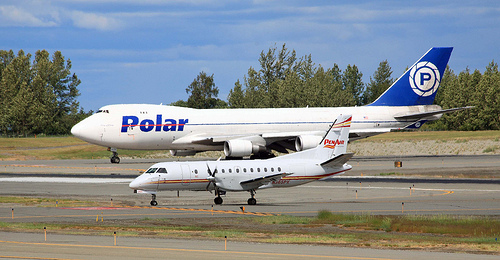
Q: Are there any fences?
A: No, there are no fences.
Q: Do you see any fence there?
A: No, there are no fences.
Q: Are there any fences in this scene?
A: No, there are no fences.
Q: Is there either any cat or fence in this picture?
A: No, there are no fences or cats.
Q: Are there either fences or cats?
A: No, there are no fences or cats.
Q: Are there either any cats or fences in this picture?
A: No, there are no fences or cats.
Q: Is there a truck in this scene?
A: No, there are no trucks.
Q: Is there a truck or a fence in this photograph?
A: No, there are no trucks or fences.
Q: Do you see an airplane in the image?
A: Yes, there is an airplane.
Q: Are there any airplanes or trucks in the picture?
A: Yes, there is an airplane.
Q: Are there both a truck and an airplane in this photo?
A: No, there is an airplane but no trucks.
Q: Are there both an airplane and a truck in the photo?
A: No, there is an airplane but no trucks.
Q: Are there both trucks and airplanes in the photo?
A: No, there is an airplane but no trucks.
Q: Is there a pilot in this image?
A: No, there are no pilots.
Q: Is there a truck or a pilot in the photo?
A: No, there are no pilots or trucks.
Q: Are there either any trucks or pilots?
A: No, there are no pilots or trucks.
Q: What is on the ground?
A: The plane is on the ground.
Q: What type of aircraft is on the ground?
A: The aircraft is an airplane.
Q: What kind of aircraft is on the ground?
A: The aircraft is an airplane.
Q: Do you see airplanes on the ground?
A: Yes, there is an airplane on the ground.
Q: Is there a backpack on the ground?
A: No, there is an airplane on the ground.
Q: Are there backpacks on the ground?
A: No, there is an airplane on the ground.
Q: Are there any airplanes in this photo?
A: Yes, there is an airplane.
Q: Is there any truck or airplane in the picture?
A: Yes, there is an airplane.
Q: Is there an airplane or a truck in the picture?
A: Yes, there is an airplane.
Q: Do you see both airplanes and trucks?
A: No, there is an airplane but no trucks.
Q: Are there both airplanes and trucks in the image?
A: No, there is an airplane but no trucks.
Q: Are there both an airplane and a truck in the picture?
A: No, there is an airplane but no trucks.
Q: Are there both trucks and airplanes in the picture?
A: No, there is an airplane but no trucks.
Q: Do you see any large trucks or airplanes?
A: Yes, there is a large airplane.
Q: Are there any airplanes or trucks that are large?
A: Yes, the airplane is large.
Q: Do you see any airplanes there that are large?
A: Yes, there is a large airplane.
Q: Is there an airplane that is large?
A: Yes, there is an airplane that is large.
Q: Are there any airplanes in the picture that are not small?
A: Yes, there is a large airplane.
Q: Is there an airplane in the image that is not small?
A: Yes, there is a large airplane.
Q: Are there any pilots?
A: No, there are no pilots.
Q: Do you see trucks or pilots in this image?
A: No, there are no pilots or trucks.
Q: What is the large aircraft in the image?
A: The aircraft is an airplane.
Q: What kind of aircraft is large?
A: The aircraft is an airplane.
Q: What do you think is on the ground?
A: The airplane is on the ground.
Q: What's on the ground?
A: The airplane is on the ground.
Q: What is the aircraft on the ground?
A: The aircraft is an airplane.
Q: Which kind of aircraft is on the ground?
A: The aircraft is an airplane.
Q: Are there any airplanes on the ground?
A: Yes, there is an airplane on the ground.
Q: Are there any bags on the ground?
A: No, there is an airplane on the ground.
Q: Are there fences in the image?
A: No, there are no fences.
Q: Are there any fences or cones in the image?
A: No, there are no fences or cones.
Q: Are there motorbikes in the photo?
A: No, there are no motorbikes.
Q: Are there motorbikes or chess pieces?
A: No, there are no motorbikes or chess pieces.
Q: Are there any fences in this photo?
A: No, there are no fences.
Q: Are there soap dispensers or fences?
A: No, there are no fences or soap dispensers.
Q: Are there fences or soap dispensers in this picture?
A: No, there are no fences or soap dispensers.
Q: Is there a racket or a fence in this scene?
A: No, there are no fences or rackets.